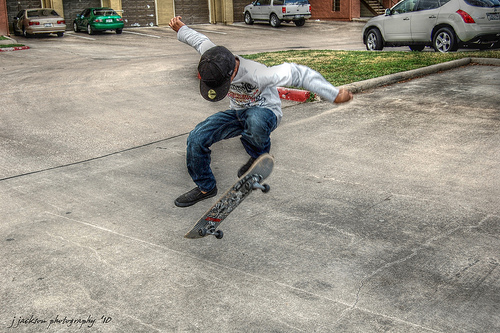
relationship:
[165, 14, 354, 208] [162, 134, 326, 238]
boy performing trick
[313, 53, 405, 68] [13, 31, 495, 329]
grass in courtyard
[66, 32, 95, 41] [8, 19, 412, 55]
line on parking area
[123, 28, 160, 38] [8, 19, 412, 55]
line on parking area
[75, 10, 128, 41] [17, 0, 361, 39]
car next to building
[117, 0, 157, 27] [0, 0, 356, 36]
door of building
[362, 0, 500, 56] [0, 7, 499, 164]
car in lot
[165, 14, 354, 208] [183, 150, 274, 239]
boy on skateboard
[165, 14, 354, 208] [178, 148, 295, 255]
boy using skateboard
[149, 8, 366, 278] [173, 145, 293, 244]
boy performing trick skateboard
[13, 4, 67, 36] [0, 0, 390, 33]
vehicles parked by building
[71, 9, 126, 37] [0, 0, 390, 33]
car parked by building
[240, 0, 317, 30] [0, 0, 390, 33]
suv parked by building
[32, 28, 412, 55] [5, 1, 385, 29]
parking area in front of building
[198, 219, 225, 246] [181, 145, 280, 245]
truck on skateboard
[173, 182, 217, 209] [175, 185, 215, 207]
shoe on foot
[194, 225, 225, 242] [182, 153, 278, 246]
wheel on skateboard